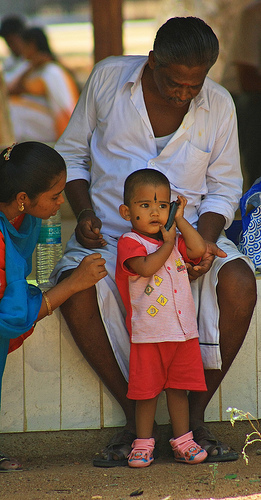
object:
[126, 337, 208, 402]
shorts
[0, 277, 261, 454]
wall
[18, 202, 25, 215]
earring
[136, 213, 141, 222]
marking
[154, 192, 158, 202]
marking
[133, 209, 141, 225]
cheek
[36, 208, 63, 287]
bottle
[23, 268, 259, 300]
ledge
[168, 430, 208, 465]
shoe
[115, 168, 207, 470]
baby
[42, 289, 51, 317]
bracelet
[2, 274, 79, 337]
arm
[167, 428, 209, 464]
feet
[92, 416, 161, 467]
sandal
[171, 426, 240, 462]
sandal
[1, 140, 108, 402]
girl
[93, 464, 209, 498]
dirt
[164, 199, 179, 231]
phone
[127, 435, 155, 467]
shoe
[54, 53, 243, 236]
shirt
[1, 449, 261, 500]
ground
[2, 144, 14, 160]
hair tie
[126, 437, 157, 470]
sandals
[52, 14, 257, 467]
man